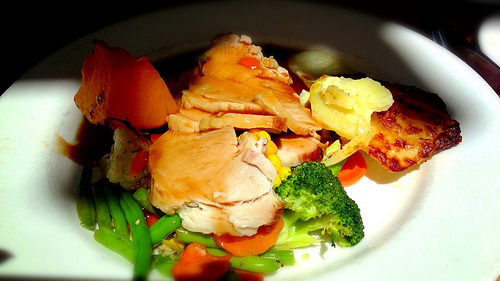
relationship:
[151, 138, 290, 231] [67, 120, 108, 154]
turkey with gravy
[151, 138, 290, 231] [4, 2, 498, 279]
turkey on plate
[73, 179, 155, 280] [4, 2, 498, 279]
beans on plate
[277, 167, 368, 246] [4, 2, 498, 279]
broccoli on plate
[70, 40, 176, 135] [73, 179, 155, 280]
carrot with beans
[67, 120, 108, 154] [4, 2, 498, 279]
gravy on plate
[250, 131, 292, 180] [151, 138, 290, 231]
corn under turkey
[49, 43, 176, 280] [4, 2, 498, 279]
vegetables on plate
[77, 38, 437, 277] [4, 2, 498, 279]
food on plate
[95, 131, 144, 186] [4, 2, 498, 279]
cauliflower on plate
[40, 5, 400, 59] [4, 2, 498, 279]
shadow on plate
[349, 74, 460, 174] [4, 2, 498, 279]
potatoes on plate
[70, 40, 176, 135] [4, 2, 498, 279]
carrot on plate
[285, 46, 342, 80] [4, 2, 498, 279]
squash on plate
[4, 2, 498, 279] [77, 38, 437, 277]
plate contains food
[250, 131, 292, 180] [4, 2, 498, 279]
corn on plate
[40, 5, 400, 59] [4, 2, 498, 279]
shadow covering plate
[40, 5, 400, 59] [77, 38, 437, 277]
shadow covering food